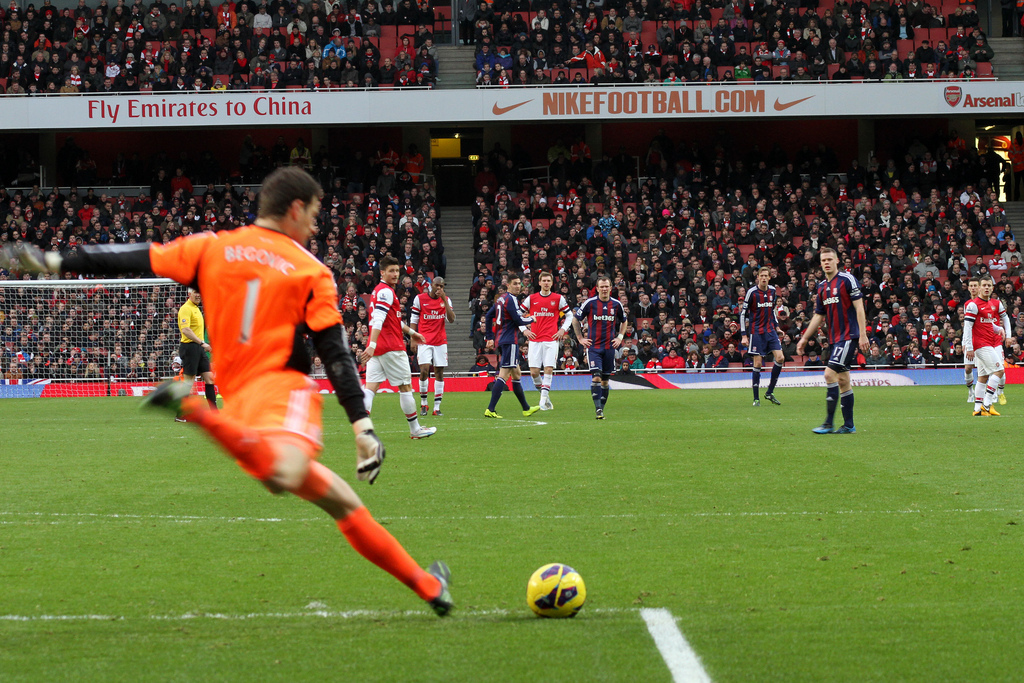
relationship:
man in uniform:
[0, 166, 455, 618] [53, 221, 447, 608]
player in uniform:
[792, 244, 878, 440] [816, 269, 871, 437]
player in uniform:
[737, 268, 798, 409] [732, 280, 796, 401]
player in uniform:
[571, 276, 652, 423] [573, 294, 635, 415]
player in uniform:
[475, 271, 547, 422] [482, 292, 545, 415]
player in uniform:
[514, 268, 577, 415] [517, 294, 572, 406]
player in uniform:
[404, 275, 460, 419] [407, 295, 464, 411]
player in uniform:
[359, 251, 440, 446] [356, 284, 443, 444]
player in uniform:
[960, 275, 1014, 420] [963, 296, 1019, 419]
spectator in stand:
[421, 240, 441, 269] [5, 135, 1021, 377]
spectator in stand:
[660, 346, 684, 370] [5, 135, 1021, 377]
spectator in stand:
[420, 239, 439, 263] [5, 135, 1021, 377]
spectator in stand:
[532, 223, 554, 247] [5, 135, 1021, 377]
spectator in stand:
[888, 175, 907, 199] [5, 135, 1021, 377]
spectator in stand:
[214, 3, 239, 29] [4, 0, 1021, 101]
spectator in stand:
[394, 35, 417, 59] [4, 0, 1021, 101]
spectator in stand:
[562, 44, 607, 71] [4, 0, 1021, 101]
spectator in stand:
[139, 42, 160, 64] [4, 0, 1021, 101]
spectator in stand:
[676, 41, 698, 65] [4, 0, 1021, 101]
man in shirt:
[172, 284, 224, 413] [163, 298, 216, 350]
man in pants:
[172, 284, 224, 413] [175, 339, 216, 381]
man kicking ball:
[0, 166, 455, 618] [523, 556, 593, 627]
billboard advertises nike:
[0, 77, 1023, 126] [482, 85, 830, 127]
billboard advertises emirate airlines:
[0, 77, 1023, 126] [70, 93, 330, 127]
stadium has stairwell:
[5, 1, 1020, 396] [428, 124, 482, 377]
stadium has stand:
[5, 1, 1020, 396] [5, 135, 1021, 377]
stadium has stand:
[5, 1, 1020, 396] [4, 0, 1021, 101]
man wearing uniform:
[0, 166, 455, 618] [53, 221, 447, 608]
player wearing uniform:
[514, 268, 577, 415] [517, 294, 572, 406]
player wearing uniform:
[404, 275, 460, 419] [407, 295, 464, 411]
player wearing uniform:
[359, 251, 440, 446] [356, 284, 443, 444]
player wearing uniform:
[960, 275, 1014, 420] [963, 296, 1019, 419]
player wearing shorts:
[359, 251, 440, 446] [361, 346, 419, 388]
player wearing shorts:
[404, 275, 460, 419] [414, 341, 456, 370]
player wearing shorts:
[514, 268, 577, 415] [522, 335, 564, 375]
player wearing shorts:
[960, 275, 1014, 420] [968, 343, 1010, 379]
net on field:
[2, 276, 210, 404] [10, 385, 1023, 682]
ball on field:
[523, 556, 593, 627] [10, 385, 1023, 682]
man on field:
[172, 284, 224, 413] [10, 385, 1023, 682]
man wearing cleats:
[0, 166, 455, 618] [138, 367, 207, 415]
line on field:
[629, 591, 723, 680] [10, 385, 1023, 682]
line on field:
[3, 500, 1022, 524] [10, 385, 1023, 682]